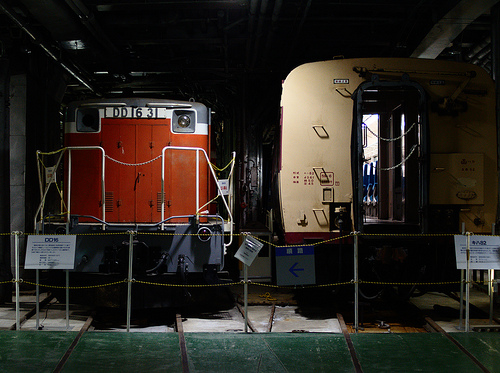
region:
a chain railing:
[6, 228, 499, 333]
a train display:
[33, 93, 238, 315]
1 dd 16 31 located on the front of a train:
[22, 92, 235, 312]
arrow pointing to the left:
[274, 247, 315, 287]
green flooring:
[3, 327, 494, 371]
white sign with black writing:
[453, 233, 498, 270]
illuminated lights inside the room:
[360, 114, 382, 223]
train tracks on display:
[13, 279, 498, 326]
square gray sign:
[272, 246, 316, 286]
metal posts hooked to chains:
[5, 225, 498, 330]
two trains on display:
[4, 6, 491, 341]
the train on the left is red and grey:
[22, 63, 269, 310]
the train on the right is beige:
[256, 55, 497, 304]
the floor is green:
[90, 329, 413, 369]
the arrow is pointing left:
[234, 215, 351, 297]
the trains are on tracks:
[16, 180, 471, 363]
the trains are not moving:
[17, 32, 484, 333]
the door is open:
[314, 58, 454, 263]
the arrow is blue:
[257, 237, 324, 294]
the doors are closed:
[75, 107, 191, 224]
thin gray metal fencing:
[3, 227, 497, 329]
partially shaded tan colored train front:
[273, 58, 485, 233]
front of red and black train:
[58, 82, 215, 319]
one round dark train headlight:
[170, 105, 199, 136]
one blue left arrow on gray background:
[275, 252, 312, 285]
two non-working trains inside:
[30, 43, 497, 360]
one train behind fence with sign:
[19, 83, 239, 338]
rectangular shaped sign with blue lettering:
[21, 232, 83, 272]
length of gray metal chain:
[98, 150, 168, 168]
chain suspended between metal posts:
[94, 149, 167, 167]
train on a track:
[35, 83, 257, 316]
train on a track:
[273, 40, 489, 307]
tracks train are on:
[10, 308, 467, 368]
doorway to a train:
[358, 90, 420, 226]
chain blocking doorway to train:
[361, 121, 423, 173]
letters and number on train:
[101, 104, 165, 124]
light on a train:
[178, 110, 198, 134]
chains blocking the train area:
[10, 225, 495, 325]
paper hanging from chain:
[224, 234, 268, 267]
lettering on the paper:
[32, 243, 69, 265]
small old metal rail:
[1, 297, 47, 333]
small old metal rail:
[55, 304, 93, 366]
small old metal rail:
[169, 310, 194, 367]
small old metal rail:
[228, 298, 260, 338]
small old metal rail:
[324, 304, 359, 371]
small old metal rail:
[406, 303, 485, 368]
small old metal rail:
[27, 142, 52, 222]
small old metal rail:
[56, 140, 78, 229]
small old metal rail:
[91, 141, 109, 234]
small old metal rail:
[153, 141, 167, 224]